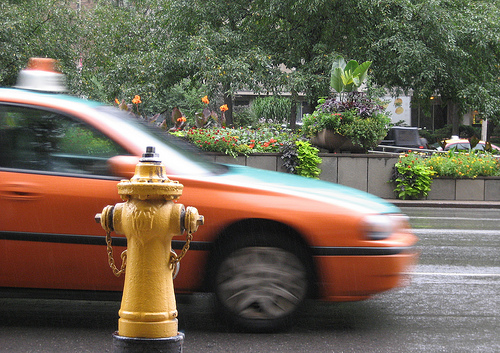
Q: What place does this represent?
A: It represents the street.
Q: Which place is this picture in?
A: It is at the street.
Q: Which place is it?
A: It is a street.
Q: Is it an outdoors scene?
A: Yes, it is outdoors.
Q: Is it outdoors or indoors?
A: It is outdoors.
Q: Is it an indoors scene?
A: No, it is outdoors.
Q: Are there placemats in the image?
A: No, there are no placemats.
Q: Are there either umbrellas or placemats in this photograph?
A: No, there are no placemats or umbrellas.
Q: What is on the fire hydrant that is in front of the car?
A: The chain is on the hydrant.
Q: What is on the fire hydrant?
A: The chain is on the hydrant.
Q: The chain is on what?
A: The chain is on the fire hydrant.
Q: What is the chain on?
A: The chain is on the fire hydrant.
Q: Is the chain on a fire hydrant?
A: Yes, the chain is on a fire hydrant.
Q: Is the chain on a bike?
A: No, the chain is on a fire hydrant.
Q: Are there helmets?
A: No, there are no helmets.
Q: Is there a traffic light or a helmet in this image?
A: No, there are no helmets or traffic lights.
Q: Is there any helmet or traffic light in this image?
A: No, there are no helmets or traffic lights.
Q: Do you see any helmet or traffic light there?
A: No, there are no helmets or traffic lights.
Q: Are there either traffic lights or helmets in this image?
A: No, there are no helmets or traffic lights.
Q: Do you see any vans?
A: No, there are no vans.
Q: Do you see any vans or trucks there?
A: No, there are no vans or trucks.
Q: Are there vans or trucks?
A: No, there are no vans or trucks.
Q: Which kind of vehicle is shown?
A: The vehicle is a car.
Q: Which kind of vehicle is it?
A: The vehicle is a car.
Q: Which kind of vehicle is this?
A: This is a car.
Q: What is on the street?
A: The car is on the street.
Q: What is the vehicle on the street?
A: The vehicle is a car.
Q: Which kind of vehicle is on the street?
A: The vehicle is a car.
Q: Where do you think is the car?
A: The car is on the street.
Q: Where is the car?
A: The car is on the street.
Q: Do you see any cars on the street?
A: Yes, there is a car on the street.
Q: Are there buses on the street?
A: No, there is a car on the street.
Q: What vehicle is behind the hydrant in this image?
A: The vehicle is a car.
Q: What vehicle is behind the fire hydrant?
A: The vehicle is a car.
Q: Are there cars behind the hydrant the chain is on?
A: Yes, there is a car behind the hydrant.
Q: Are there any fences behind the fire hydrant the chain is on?
A: No, there is a car behind the fire hydrant.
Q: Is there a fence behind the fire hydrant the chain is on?
A: No, there is a car behind the fire hydrant.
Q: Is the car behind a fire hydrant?
A: Yes, the car is behind a fire hydrant.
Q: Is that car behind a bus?
A: No, the car is behind a fire hydrant.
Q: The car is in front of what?
A: The car is in front of the plant.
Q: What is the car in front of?
A: The car is in front of the plant.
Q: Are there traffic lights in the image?
A: No, there are no traffic lights.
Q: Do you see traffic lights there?
A: No, there are no traffic lights.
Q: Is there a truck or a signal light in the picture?
A: No, there are no traffic lights or trucks.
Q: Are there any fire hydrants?
A: Yes, there is a fire hydrant.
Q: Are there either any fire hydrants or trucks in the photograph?
A: Yes, there is a fire hydrant.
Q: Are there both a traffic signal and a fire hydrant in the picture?
A: No, there is a fire hydrant but no traffic lights.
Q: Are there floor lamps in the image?
A: No, there are no floor lamps.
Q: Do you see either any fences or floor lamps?
A: No, there are no floor lamps or fences.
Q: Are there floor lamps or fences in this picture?
A: No, there are no floor lamps or fences.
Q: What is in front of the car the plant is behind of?
A: The hydrant is in front of the car.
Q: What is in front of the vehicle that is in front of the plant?
A: The hydrant is in front of the car.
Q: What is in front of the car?
A: The hydrant is in front of the car.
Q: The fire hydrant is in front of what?
A: The fire hydrant is in front of the car.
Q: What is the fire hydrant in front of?
A: The fire hydrant is in front of the car.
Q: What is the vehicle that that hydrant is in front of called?
A: The vehicle is a car.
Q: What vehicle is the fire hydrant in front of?
A: The hydrant is in front of the car.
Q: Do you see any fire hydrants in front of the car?
A: Yes, there is a fire hydrant in front of the car.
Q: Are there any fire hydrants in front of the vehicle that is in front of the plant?
A: Yes, there is a fire hydrant in front of the car.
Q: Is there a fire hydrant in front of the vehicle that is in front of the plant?
A: Yes, there is a fire hydrant in front of the car.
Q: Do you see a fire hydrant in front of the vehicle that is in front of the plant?
A: Yes, there is a fire hydrant in front of the car.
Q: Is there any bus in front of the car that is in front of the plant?
A: No, there is a fire hydrant in front of the car.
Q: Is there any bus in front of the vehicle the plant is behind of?
A: No, there is a fire hydrant in front of the car.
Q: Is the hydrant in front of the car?
A: Yes, the hydrant is in front of the car.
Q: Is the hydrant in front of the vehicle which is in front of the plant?
A: Yes, the hydrant is in front of the car.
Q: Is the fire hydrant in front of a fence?
A: No, the fire hydrant is in front of the car.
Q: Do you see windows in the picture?
A: Yes, there is a window.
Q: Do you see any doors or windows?
A: Yes, there is a window.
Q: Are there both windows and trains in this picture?
A: No, there is a window but no trains.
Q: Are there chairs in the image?
A: No, there are no chairs.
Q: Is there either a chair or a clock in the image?
A: No, there are no chairs or clocks.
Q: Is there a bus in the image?
A: No, there are no buses.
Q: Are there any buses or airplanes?
A: No, there are no buses or airplanes.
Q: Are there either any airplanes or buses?
A: No, there are no buses or airplanes.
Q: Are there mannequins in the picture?
A: No, there are no mannequins.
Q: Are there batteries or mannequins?
A: No, there are no mannequins or batteries.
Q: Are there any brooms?
A: No, there are no brooms.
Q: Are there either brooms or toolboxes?
A: No, there are no brooms or toolboxes.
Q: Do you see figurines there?
A: No, there are no figurines.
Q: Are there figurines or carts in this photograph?
A: No, there are no figurines or carts.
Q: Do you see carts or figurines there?
A: No, there are no figurines or carts.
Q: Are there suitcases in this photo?
A: No, there are no suitcases.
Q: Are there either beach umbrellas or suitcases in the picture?
A: No, there are no suitcases or beach umbrellas.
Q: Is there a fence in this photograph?
A: No, there are no fences.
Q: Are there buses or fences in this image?
A: No, there are no fences or buses.